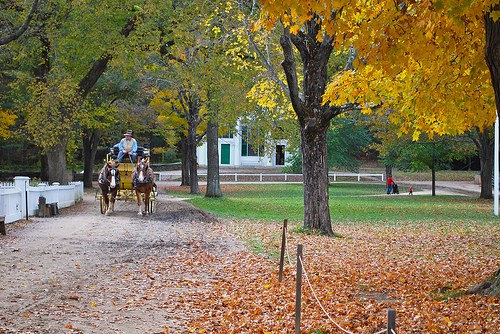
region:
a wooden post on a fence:
[270, 217, 292, 284]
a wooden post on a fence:
[383, 304, 395, 332]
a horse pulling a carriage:
[95, 159, 120, 213]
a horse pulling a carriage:
[130, 155, 157, 221]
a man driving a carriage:
[114, 125, 143, 166]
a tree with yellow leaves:
[218, 3, 498, 238]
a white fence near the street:
[0, 174, 85, 231]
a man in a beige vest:
[117, 127, 139, 170]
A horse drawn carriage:
[97, 127, 159, 216]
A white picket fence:
[2, 175, 84, 225]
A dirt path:
[1, 181, 247, 331]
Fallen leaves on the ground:
[117, 216, 498, 332]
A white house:
[194, 102, 300, 168]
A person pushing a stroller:
[384, 175, 400, 192]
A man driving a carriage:
[115, 128, 138, 163]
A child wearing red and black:
[407, 186, 413, 194]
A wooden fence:
[277, 217, 402, 332]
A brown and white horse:
[129, 155, 154, 216]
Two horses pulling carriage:
[86, 127, 170, 222]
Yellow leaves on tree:
[281, 1, 491, 136]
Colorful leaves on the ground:
[205, 209, 498, 331]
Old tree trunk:
[291, 42, 349, 231]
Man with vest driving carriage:
[111, 128, 141, 159]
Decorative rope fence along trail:
[261, 226, 388, 331]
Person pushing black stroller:
[380, 173, 406, 194]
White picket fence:
[2, 169, 97, 218]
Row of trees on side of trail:
[162, 3, 344, 266]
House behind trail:
[191, 92, 321, 182]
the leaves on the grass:
[347, 243, 413, 269]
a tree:
[297, 139, 335, 233]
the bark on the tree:
[302, 164, 327, 219]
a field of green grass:
[356, 195, 434, 220]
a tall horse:
[102, 164, 118, 205]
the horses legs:
[129, 192, 156, 219]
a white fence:
[11, 184, 33, 214]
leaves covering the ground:
[321, 223, 436, 295]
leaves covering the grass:
[381, 193, 463, 275]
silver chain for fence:
[297, 281, 347, 313]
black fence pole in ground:
[284, 242, 316, 319]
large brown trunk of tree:
[287, 16, 342, 238]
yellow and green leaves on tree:
[367, 31, 459, 131]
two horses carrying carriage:
[98, 165, 155, 217]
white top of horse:
[127, 161, 152, 191]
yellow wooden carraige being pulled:
[118, 162, 145, 186]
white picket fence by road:
[0, 183, 78, 210]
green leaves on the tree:
[153, 56, 186, 79]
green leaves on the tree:
[229, 93, 250, 127]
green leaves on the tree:
[181, 31, 221, 76]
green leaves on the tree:
[159, 1, 227, 63]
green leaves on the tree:
[131, 3, 176, 60]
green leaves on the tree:
[76, 3, 116, 65]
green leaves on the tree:
[410, 153, 428, 173]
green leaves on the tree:
[333, 134, 353, 165]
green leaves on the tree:
[37, 81, 75, 157]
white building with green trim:
[195, 99, 310, 170]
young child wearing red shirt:
[406, 184, 413, 195]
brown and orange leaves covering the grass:
[193, 218, 498, 328]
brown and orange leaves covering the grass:
[157, 181, 262, 193]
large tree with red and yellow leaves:
[214, 27, 499, 236]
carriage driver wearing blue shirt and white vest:
[113, 127, 139, 163]